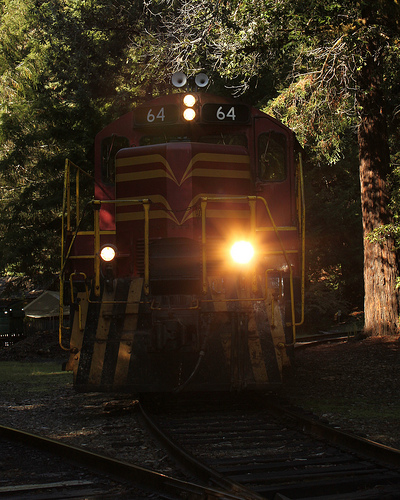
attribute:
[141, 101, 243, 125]
numbers — white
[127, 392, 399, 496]
track — train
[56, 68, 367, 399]
train — travelling, moving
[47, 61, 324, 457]
train — passing by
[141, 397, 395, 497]
tracks — railroad, set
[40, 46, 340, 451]
train — large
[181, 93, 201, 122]
headlights — top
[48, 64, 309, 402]
train — red, yellow, moving, couple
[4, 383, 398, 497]
track — empty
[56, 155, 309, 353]
hand rail — yellow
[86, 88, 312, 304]
headlights — on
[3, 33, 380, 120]
tree — tall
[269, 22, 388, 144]
trees — large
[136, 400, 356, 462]
tracks — two sets, railroad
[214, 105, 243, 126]
numbers — white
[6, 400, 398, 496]
tracks — train, two sets